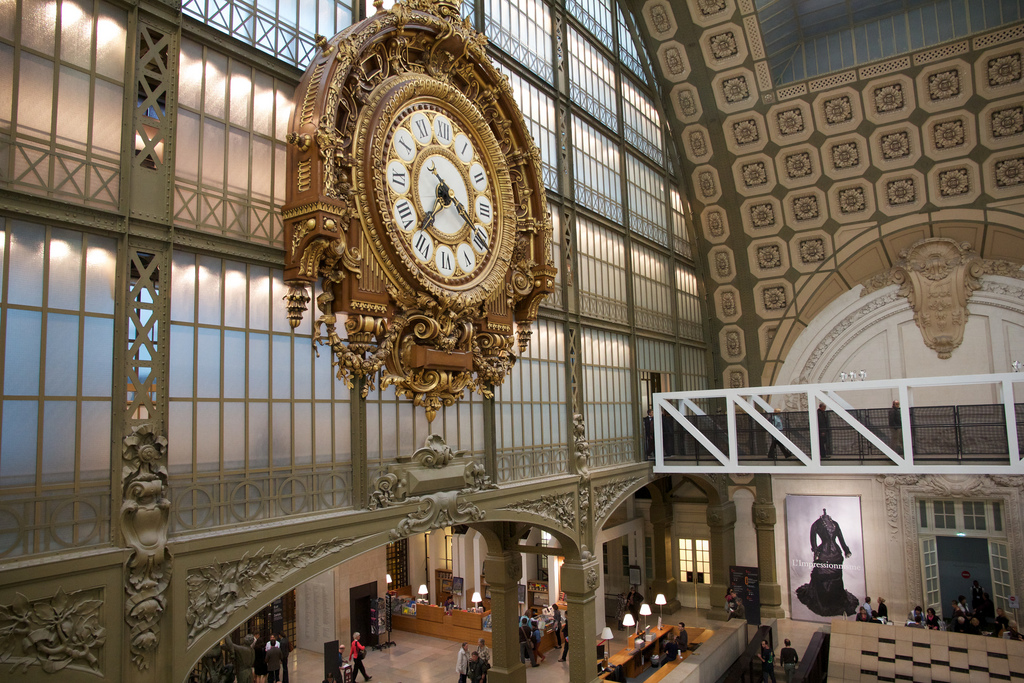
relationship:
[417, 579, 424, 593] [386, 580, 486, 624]
lamp standing on desk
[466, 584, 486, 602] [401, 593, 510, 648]
lamp standing on desk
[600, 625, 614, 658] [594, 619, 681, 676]
lamp standing on desk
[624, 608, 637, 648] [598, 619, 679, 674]
lamp standing on desk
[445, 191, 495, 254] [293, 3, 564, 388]
hand of clock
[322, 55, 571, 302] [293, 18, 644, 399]
numbers on clock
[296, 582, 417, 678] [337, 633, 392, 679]
woman wearing shirt